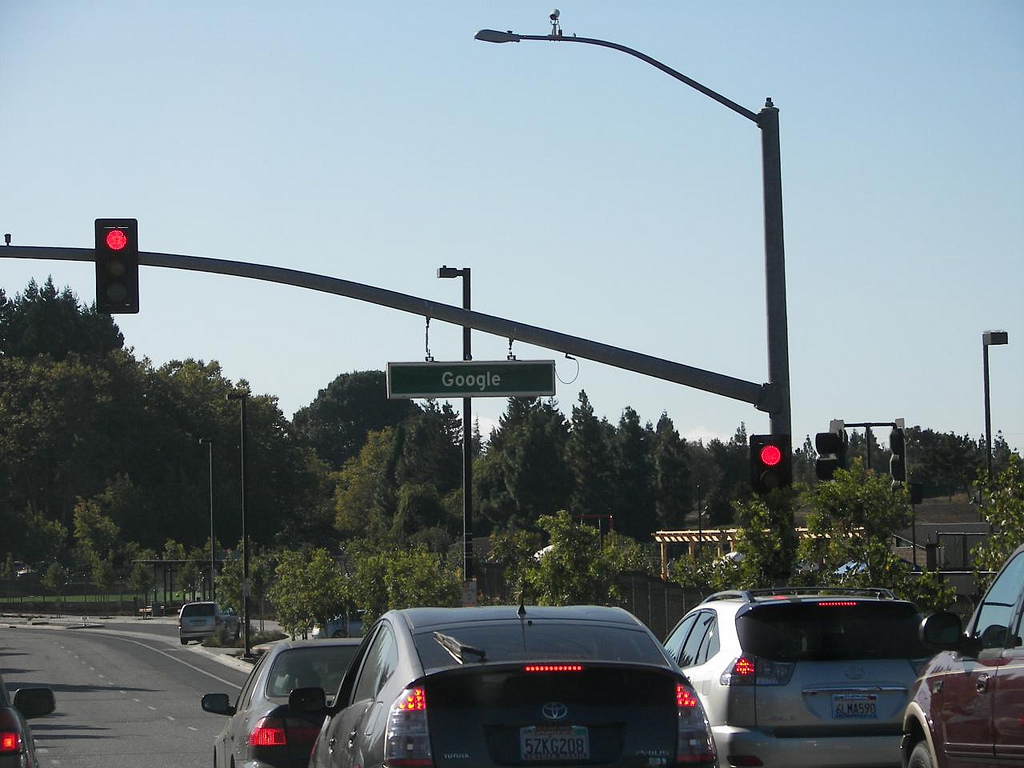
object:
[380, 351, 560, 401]
street sign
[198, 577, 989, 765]
group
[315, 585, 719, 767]
car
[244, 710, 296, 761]
light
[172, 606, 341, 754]
car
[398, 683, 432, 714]
light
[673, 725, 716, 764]
light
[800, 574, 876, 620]
light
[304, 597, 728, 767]
car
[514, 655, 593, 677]
light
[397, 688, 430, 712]
light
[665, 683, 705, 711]
light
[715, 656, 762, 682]
light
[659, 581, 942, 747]
car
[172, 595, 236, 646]
car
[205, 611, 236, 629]
light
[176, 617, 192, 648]
light